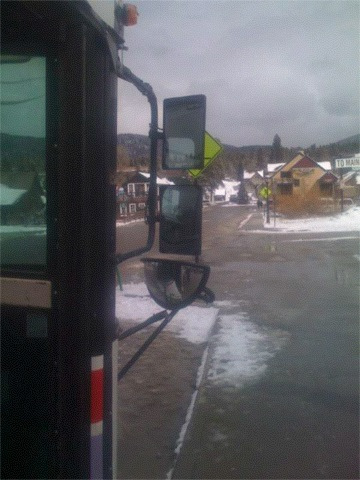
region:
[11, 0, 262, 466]
a vehicle is going through slush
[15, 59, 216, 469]
the bus has side rear view mirrors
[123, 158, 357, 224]
snow is on the roofs of houses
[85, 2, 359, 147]
the sky is gray and cloudy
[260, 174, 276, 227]
a street lamp is on the side of the road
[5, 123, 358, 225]
mountains are in the distance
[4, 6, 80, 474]
the bus door is open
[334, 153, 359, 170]
a directional sign is on a roadway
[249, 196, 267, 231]
a couple is walking on the sidewalk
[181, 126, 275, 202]
yellow caution signs are on the street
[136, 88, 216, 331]
several mirrors on a bus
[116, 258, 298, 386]
melting snow on the street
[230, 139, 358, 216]
a group of houses on the street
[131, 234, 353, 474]
a wet street in the neighborhood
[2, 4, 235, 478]
a bus driving through the neighborhood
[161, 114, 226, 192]
a yellow warning sign on the street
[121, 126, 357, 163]
hills that are located behind the houses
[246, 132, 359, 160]
large trees that grow on the hills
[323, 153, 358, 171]
a white and black street sign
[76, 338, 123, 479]
red, white and blue design on the bus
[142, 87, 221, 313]
three side mirrors on bus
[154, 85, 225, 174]
one mirror on bus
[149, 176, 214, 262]
one mirror on bus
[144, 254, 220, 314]
one mirror on bus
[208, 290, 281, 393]
white patch of snow on the road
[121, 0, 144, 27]
light on the bus roof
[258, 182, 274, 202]
four sided yellow traffic signal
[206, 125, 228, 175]
yellow traffic signal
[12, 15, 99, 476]
open bus door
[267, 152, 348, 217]
brown two story house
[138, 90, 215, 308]
gray mirror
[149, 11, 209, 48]
white clouds in blue sky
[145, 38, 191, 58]
white clouds in blue sky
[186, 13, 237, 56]
white clouds in blue sky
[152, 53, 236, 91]
white clouds in blue sky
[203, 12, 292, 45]
white clouds in blue sky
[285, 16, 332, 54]
white clouds in blue sky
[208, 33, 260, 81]
white clouds in blue sky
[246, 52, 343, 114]
white clouds in blue sky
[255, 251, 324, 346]
water on street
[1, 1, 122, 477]
Door on a bus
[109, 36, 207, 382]
Three side mirrors on a bus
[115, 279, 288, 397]
Patches of snow and ice on the road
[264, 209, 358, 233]
Snow piled up in a yard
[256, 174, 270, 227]
Street light and sign beside a sidewalk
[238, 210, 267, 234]
Sidewalk cleaned of snow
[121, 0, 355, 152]
Cloudy gray sky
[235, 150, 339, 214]
Houses beside a road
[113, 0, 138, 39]
Orange light on a bus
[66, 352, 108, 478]
Red and purple stripe beside a bus door